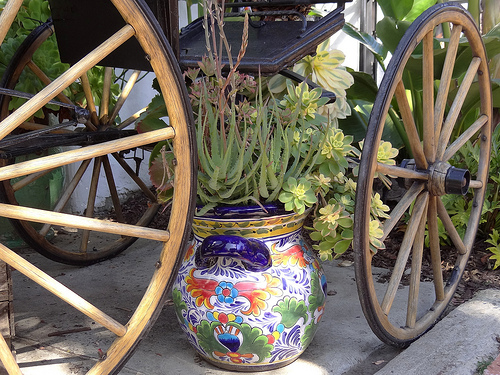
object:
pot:
[168, 205, 326, 370]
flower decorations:
[235, 280, 272, 311]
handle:
[196, 235, 270, 268]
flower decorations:
[193, 320, 264, 362]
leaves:
[486, 246, 500, 254]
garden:
[399, 0, 498, 267]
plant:
[199, 66, 354, 200]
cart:
[0, 1, 488, 375]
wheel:
[355, 5, 492, 348]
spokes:
[420, 35, 437, 157]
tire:
[354, 165, 367, 310]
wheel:
[1, 1, 196, 373]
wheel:
[2, 22, 159, 265]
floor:
[143, 340, 499, 375]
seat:
[173, 19, 342, 64]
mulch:
[467, 260, 490, 287]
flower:
[294, 85, 316, 119]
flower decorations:
[200, 263, 249, 279]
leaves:
[343, 19, 382, 58]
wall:
[339, 3, 360, 66]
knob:
[441, 165, 471, 197]